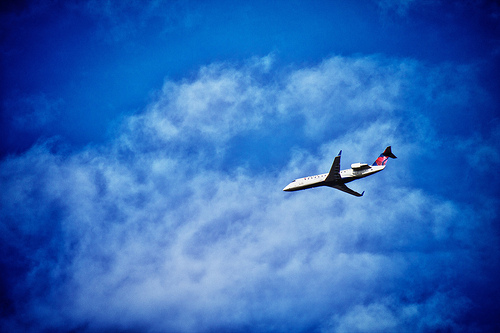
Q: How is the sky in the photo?
A: Blue and cloudy.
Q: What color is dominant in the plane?
A: White.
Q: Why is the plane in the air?
A: It is flying.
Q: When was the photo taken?
A: Daytime.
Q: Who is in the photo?
A: Noone.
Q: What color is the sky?
A: Blue.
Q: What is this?
A: A plane.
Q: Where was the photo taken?
A: In mid air.